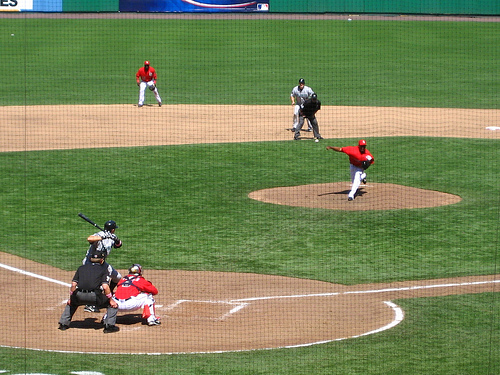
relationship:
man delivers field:
[326, 138, 377, 201] [0, 5, 496, 375]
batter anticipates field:
[76, 211, 124, 266] [0, 5, 496, 375]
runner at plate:
[289, 76, 322, 134] [290, 124, 316, 135]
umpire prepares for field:
[55, 249, 124, 335] [0, 5, 496, 375]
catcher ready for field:
[104, 261, 160, 329] [0, 5, 496, 375]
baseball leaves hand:
[314, 136, 320, 143] [323, 144, 332, 152]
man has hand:
[326, 138, 377, 201] [323, 144, 332, 152]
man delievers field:
[326, 138, 377, 201] [0, 5, 496, 375]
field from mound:
[0, 5, 496, 375] [245, 171, 463, 215]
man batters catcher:
[326, 138, 377, 201] [104, 261, 160, 329]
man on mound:
[326, 138, 377, 201] [245, 171, 463, 215]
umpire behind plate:
[55, 249, 124, 335] [104, 290, 160, 313]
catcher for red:
[135, 66, 159, 84] [137, 65, 161, 85]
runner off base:
[289, 76, 322, 134] [483, 124, 499, 135]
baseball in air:
[314, 136, 320, 143] [6, 5, 498, 366]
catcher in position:
[104, 261, 160, 329] [100, 266, 160, 326]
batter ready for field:
[76, 211, 124, 266] [0, 5, 496, 375]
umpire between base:
[55, 249, 124, 335] [483, 124, 499, 135]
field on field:
[0, 5, 496, 375] [4, 5, 496, 372]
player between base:
[289, 76, 322, 134] [483, 124, 499, 135]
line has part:
[0, 260, 500, 316] [2, 248, 75, 300]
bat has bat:
[78, 212, 109, 233] [78, 212, 109, 233]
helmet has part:
[99, 217, 124, 233] [114, 223, 122, 228]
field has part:
[0, 5, 496, 375] [0, 84, 499, 155]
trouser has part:
[115, 293, 156, 331] [112, 293, 156, 331]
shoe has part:
[145, 316, 164, 324] [145, 320, 155, 325]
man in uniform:
[326, 138, 377, 201] [337, 148, 375, 193]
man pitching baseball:
[326, 138, 377, 201] [314, 136, 320, 143]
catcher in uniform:
[104, 261, 160, 329] [114, 273, 164, 318]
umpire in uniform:
[55, 249, 124, 335] [55, 249, 124, 335]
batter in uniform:
[76, 211, 124, 266] [80, 230, 125, 266]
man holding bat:
[76, 211, 124, 266] [79, 208, 109, 233]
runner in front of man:
[289, 76, 322, 134] [289, 76, 322, 134]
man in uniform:
[289, 76, 322, 134] [292, 87, 316, 125]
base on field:
[483, 124, 499, 135] [4, 5, 496, 372]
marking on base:
[159, 292, 245, 325] [97, 285, 242, 330]